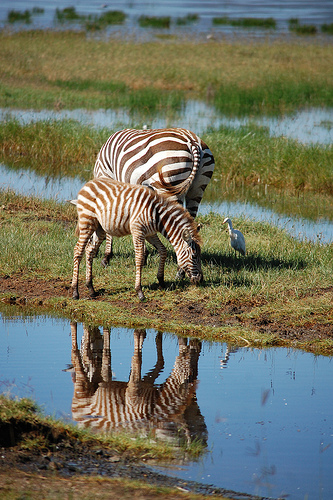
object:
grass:
[0, 1, 333, 499]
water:
[0, 293, 332, 497]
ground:
[0, 0, 333, 498]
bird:
[222, 217, 246, 264]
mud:
[0, 418, 156, 486]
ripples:
[5, 323, 185, 395]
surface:
[1, 94, 333, 149]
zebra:
[88, 126, 216, 264]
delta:
[0, 94, 332, 499]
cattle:
[71, 125, 216, 301]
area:
[0, 3, 333, 498]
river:
[0, 311, 333, 499]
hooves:
[72, 274, 166, 301]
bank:
[0, 268, 333, 352]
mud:
[2, 274, 40, 296]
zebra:
[72, 176, 204, 302]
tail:
[151, 143, 200, 200]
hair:
[155, 182, 205, 250]